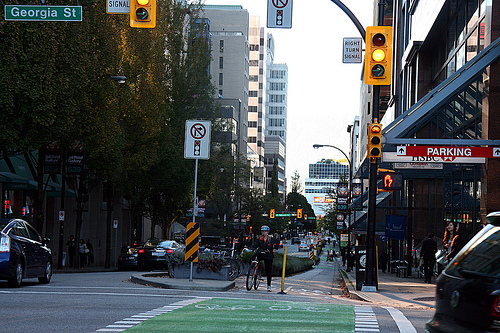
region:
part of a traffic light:
[360, 45, 398, 101]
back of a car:
[435, 238, 482, 318]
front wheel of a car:
[43, 250, 58, 284]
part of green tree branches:
[57, 109, 156, 194]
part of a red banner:
[395, 142, 487, 165]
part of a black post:
[366, 157, 379, 288]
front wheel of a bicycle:
[241, 255, 256, 293]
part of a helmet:
[260, 223, 270, 230]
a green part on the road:
[229, 286, 315, 322]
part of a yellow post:
[281, 249, 295, 296]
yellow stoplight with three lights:
[360, 26, 403, 91]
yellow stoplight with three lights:
[361, 116, 396, 174]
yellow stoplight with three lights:
[261, 202, 313, 226]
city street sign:
[168, 110, 228, 274]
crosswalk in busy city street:
[143, 272, 358, 331]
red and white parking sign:
[389, 131, 499, 171]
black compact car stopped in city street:
[138, 236, 183, 271]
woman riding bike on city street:
[235, 222, 284, 293]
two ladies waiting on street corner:
[426, 213, 475, 283]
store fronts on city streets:
[1, 161, 129, 262]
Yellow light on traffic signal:
[347, 16, 406, 92]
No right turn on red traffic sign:
[171, 106, 220, 168]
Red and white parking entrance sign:
[395, 137, 498, 174]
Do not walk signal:
[372, 163, 404, 199]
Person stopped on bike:
[245, 225, 285, 295]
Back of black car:
[413, 239, 496, 329]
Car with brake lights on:
[131, 234, 182, 273]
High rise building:
[261, 47, 293, 212]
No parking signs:
[33, 197, 140, 240]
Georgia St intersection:
[0, 3, 417, 313]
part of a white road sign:
[178, 113, 215, 167]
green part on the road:
[266, 294, 301, 321]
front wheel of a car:
[38, 255, 54, 285]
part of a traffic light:
[374, 42, 394, 99]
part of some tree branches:
[56, 47, 146, 172]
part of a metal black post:
[360, 155, 381, 297]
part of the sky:
[306, 27, 333, 104]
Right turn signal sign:
[340, 33, 362, 68]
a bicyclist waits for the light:
[241, 224, 282, 295]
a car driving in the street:
[1, 213, 57, 302]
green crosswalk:
[168, 268, 383, 330]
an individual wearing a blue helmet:
[256, 223, 273, 238]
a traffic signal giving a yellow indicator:
[364, 23, 399, 87]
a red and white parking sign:
[395, 135, 499, 157]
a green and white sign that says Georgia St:
[0, 4, 88, 21]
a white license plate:
[148, 249, 163, 256]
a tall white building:
[264, 62, 294, 237]